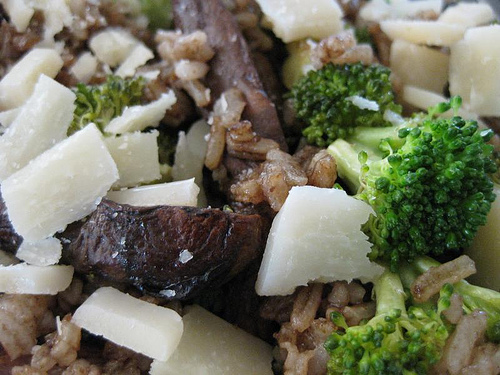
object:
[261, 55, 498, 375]
broccoli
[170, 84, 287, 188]
rice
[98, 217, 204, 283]
mushroom top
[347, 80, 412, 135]
flecks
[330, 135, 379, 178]
stem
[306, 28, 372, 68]
rice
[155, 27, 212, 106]
rice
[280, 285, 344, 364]
rice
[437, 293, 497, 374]
rice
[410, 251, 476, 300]
rice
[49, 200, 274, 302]
mushroom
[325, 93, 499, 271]
broccoli piece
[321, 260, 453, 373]
broccoli piece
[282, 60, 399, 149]
broccoli piece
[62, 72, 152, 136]
broccoli piece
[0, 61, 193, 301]
vegetable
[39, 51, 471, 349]
dish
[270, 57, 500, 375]
vegetable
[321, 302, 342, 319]
hair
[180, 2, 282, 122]
meat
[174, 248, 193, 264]
spot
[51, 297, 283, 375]
vegetables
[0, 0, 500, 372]
stir fry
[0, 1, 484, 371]
food